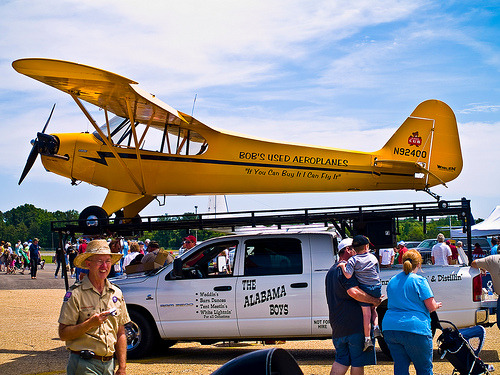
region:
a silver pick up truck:
[112, 227, 490, 348]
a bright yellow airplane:
[2, 56, 466, 233]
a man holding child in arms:
[325, 234, 380, 374]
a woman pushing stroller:
[377, 250, 487, 372]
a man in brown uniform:
[56, 240, 132, 373]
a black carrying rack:
[44, 198, 471, 280]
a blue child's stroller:
[433, 316, 492, 371]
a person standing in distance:
[430, 229, 450, 264]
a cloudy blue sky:
[2, 0, 499, 208]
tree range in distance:
[0, 203, 228, 254]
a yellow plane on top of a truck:
[8, 56, 464, 227]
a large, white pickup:
[102, 232, 489, 360]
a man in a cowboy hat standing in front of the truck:
[56, 239, 129, 373]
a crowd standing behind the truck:
[0, 235, 154, 278]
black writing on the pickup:
[193, 276, 290, 321]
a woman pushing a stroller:
[379, 249, 496, 373]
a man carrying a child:
[325, 235, 385, 372]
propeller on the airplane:
[16, 101, 58, 186]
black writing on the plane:
[234, 143, 429, 183]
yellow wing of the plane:
[13, 56, 204, 144]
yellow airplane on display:
[8, 56, 480, 280]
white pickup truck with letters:
[76, 223, 489, 357]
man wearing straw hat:
[58, 238, 132, 374]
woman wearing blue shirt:
[377, 248, 441, 373]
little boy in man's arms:
[323, 233, 384, 373]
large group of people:
[1, 238, 52, 278]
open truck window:
[171, 239, 238, 277]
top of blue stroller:
[429, 315, 494, 374]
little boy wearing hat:
[337, 231, 384, 350]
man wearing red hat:
[181, 230, 203, 266]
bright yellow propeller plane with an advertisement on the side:
[8, 48, 465, 234]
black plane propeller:
[15, 96, 60, 191]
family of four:
[323, 231, 497, 373]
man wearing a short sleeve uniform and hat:
[56, 237, 133, 373]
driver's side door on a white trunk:
[155, 228, 245, 345]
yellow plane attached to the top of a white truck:
[0, 43, 499, 373]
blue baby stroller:
[433, 314, 496, 373]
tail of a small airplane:
[376, 93, 481, 193]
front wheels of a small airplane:
[69, 191, 166, 236]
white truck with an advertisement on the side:
[106, 215, 489, 362]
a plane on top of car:
[11, 45, 467, 339]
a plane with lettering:
[224, 131, 360, 188]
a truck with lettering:
[217, 246, 317, 328]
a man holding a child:
[332, 239, 376, 357]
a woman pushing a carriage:
[393, 247, 483, 373]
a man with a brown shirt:
[40, 225, 139, 361]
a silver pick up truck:
[124, 233, 329, 342]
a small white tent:
[473, 201, 498, 239]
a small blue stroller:
[428, 296, 489, 372]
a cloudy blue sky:
[211, 66, 391, 118]